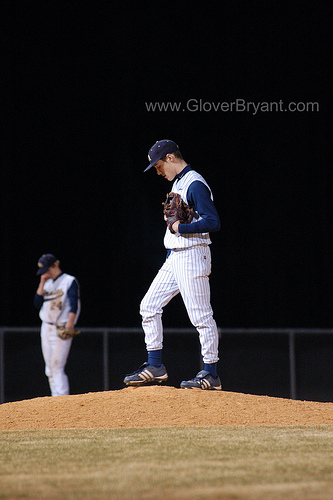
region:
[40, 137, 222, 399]
the men play baseball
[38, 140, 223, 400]
the men are looking down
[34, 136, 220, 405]
the uniform is white and blue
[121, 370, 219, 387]
the man wears cleats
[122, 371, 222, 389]
the sneakers have stripes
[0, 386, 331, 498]
the man stands on the mound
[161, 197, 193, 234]
the man holds a glove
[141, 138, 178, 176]
the man wears a hat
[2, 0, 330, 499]
the scene takes place outdoors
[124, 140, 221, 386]
the man wears a uniform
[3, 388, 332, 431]
A mound of brown dirt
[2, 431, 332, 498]
Grass by the pitcher's mound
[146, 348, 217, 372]
The pitcher has blue socks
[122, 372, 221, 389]
The pitcher has white and black shoes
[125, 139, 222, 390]
A pitcher on the mound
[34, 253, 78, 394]
Another player near the pitcher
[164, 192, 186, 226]
A glove on the left hand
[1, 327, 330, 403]
A fence behind the players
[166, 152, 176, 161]
The left ear of the player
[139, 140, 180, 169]
The pitcher is wearing a hat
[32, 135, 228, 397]
two players on ball field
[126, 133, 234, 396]
player on hill of dirt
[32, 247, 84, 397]
player in far view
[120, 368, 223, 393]
athletic sneakers on player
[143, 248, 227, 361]
pants worn by player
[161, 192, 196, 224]
baseball mitt in player's hand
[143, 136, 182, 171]
cap on player's head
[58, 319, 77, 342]
mitt in another player's hand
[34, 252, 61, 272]
cap on other player's head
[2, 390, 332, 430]
mound of dirt player stands in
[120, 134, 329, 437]
pitcher standing on top of dirt pitcher's mound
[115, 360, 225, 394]
black and white cleats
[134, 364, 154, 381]
three stripe adidas logo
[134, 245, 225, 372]
pair of blue and white pin stripe pants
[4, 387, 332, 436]
dirt pitcher's mound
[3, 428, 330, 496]
green patch of grass in front of pitcher's mound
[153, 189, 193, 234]
brown leather catcher's mitt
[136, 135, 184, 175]
black and white baseball cap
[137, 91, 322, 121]
website address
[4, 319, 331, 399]
tall metal fence in back of pitcher's mound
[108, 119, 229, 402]
man standing on a pitcher's mound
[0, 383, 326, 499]
pitcher's mound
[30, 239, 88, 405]
baseball player tilting head down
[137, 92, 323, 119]
website lettering above the pitcher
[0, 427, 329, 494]
baseball field turf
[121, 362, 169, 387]
baseball shoe on the man's right foot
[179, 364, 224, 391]
baseball shoe on the man's left foot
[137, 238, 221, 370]
white baseball uniform pants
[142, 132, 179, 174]
dark blue baseball hat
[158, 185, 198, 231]
glove in the pitcher's left hand